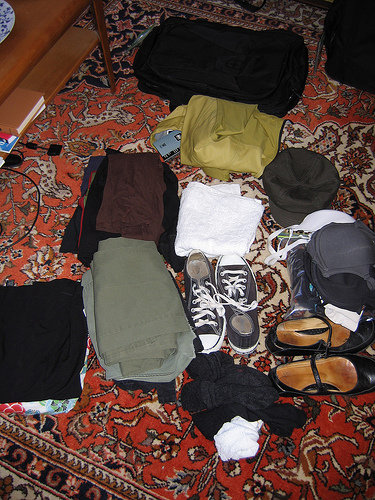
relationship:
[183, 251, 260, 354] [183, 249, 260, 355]
pair of shoes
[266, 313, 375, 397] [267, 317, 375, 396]
pair of dress shoes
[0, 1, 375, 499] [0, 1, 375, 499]
rug style oriental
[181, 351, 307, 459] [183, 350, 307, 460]
socks in a pile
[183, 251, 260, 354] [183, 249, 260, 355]
converse style shoes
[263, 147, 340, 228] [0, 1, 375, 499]
hat on rug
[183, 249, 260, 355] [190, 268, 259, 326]
shoes have shoelaces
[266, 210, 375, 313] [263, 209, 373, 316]
bras in a pile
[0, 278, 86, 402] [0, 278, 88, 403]
folded item color of black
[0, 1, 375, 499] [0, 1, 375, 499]
rug has red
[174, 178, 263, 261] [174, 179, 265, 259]
folded white item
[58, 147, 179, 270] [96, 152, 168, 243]
stack of folded shirt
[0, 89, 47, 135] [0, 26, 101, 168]
book on a piece of wood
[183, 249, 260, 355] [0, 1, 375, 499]
shoes on rug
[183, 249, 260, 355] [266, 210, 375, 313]
shoes near bras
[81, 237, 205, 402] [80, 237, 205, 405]
pants in a stack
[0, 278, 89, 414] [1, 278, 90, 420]
shorts in a stack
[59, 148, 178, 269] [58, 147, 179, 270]
shirts in a stack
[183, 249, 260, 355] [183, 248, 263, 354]
shoes have white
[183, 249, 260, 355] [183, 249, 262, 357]
shoes have black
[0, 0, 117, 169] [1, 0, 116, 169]
table made of wood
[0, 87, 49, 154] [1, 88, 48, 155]
books in a stack